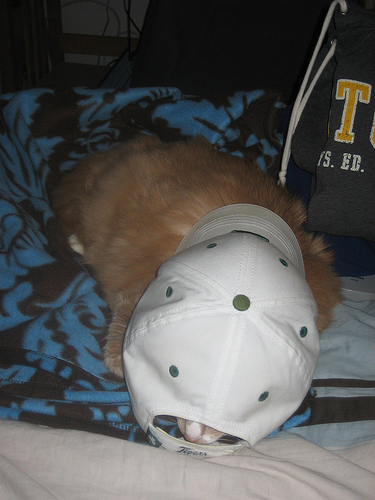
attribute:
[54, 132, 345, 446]
cat — brown, tan, sleeping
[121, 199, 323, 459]
hat — white, green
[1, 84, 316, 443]
blanket — blue, brown, floral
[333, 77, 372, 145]
letter — yellow, t, white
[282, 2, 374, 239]
shirt — gray, folded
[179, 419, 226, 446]
nose — white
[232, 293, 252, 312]
button — gray, green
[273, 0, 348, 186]
string — white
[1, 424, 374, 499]
sheet — white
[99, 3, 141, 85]
cords — black